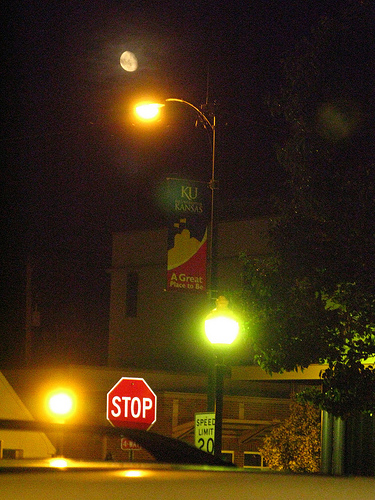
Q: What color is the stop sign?
A: Red.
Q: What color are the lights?
A: Yellow.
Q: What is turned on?
A: The lights.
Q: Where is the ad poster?
A: On the pole.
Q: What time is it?
A: Night.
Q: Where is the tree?
A: On the street.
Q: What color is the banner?
A: Red, white and blue.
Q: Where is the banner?
A: Hanging from street light.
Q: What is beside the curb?
A: Tall tree.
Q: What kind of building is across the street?
A: Brick building.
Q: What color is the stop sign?
A: Red.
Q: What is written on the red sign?
A: Stop.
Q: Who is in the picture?
A: No one.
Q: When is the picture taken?
A: Nighttime.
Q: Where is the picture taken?
A: Kansas.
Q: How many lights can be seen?
A: 3.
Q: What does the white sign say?
A: Speed limit 20.